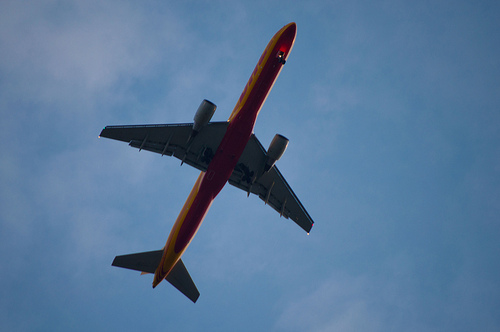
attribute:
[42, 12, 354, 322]
airplane — red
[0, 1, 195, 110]
cloud — white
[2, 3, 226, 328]
clouds — white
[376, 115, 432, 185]
ground — thin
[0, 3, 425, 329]
clouds — white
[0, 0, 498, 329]
sky — blue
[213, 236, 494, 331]
clouds — white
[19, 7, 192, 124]
clouds — white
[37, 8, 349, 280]
clouds — white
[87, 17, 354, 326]
airplane — red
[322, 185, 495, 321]
clouds — white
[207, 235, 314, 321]
clouds — white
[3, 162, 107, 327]
clouds — white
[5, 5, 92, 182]
clouds — white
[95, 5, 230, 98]
clouds — white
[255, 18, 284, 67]
light — red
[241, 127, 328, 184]
engine — jet engine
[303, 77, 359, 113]
clouds — white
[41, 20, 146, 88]
clouds — white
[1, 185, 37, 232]
clouds — white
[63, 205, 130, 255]
clouds — white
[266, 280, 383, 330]
clouds — white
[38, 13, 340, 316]
plane — red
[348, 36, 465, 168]
sky — blue and white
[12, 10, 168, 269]
cloud — white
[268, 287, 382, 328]
cloud — white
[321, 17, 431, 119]
cloud — white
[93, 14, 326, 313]
airplane — red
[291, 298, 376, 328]
clouds — white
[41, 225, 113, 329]
sky — blue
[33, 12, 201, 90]
clouds — white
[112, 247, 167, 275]
wings — small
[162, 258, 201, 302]
wings — small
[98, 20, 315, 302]
plane — large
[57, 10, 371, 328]
airplane — red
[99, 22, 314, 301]
airplane — red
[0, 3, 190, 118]
clouds — white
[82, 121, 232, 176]
wing — white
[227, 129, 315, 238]
wing — white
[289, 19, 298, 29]
point — sharp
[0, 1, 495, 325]
clouds — thin, white